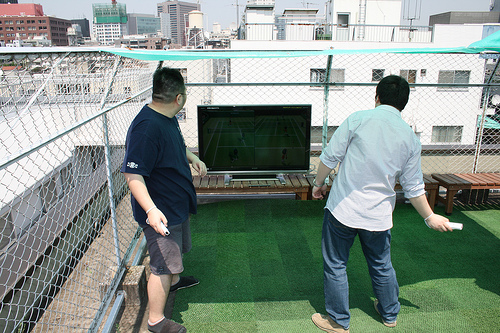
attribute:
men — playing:
[123, 72, 459, 308]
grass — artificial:
[193, 208, 499, 319]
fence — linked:
[15, 70, 163, 323]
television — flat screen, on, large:
[185, 99, 321, 176]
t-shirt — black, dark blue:
[129, 128, 199, 227]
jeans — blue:
[322, 225, 404, 320]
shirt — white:
[334, 115, 426, 224]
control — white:
[427, 217, 468, 236]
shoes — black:
[141, 314, 192, 331]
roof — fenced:
[36, 191, 500, 304]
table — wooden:
[183, 172, 313, 210]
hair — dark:
[383, 81, 409, 108]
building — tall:
[125, 43, 498, 156]